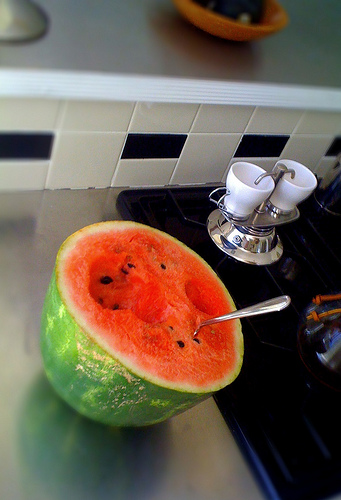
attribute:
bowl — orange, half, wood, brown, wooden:
[171, 1, 289, 43]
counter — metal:
[0, 0, 338, 112]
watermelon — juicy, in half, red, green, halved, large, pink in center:
[38, 221, 245, 433]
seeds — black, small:
[92, 261, 222, 351]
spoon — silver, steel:
[188, 295, 291, 337]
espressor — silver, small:
[208, 159, 318, 264]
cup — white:
[225, 162, 273, 218]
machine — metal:
[208, 163, 301, 265]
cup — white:
[271, 158, 317, 214]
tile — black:
[1, 129, 56, 162]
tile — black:
[118, 130, 186, 160]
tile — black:
[234, 132, 291, 159]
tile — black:
[325, 134, 339, 161]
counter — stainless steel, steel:
[0, 186, 276, 499]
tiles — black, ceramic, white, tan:
[0, 96, 338, 193]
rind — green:
[43, 268, 246, 430]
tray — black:
[108, 186, 337, 500]